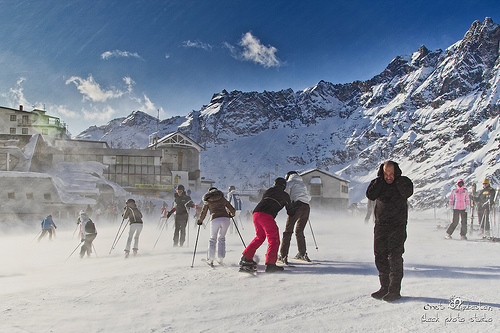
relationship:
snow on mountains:
[0, 208, 500, 332] [74, 14, 500, 211]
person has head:
[445, 177, 478, 245] [455, 177, 468, 189]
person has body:
[445, 177, 478, 245] [449, 188, 470, 209]